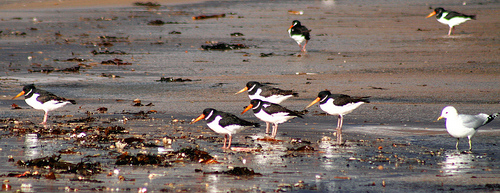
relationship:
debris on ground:
[0, 113, 270, 188] [1, 2, 498, 189]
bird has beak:
[431, 104, 495, 153] [435, 113, 444, 123]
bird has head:
[431, 104, 495, 153] [441, 103, 458, 119]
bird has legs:
[187, 107, 263, 147] [331, 112, 349, 138]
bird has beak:
[231, 92, 308, 139] [235, 94, 263, 123]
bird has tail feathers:
[431, 104, 495, 153] [478, 109, 497, 127]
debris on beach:
[63, 40, 206, 87] [7, 3, 447, 191]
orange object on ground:
[368, 140, 389, 155] [1, 2, 498, 189]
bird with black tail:
[437, 104, 499, 156] [485, 110, 498, 122]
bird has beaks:
[187, 107, 263, 147] [188, 113, 205, 124]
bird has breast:
[187, 87, 249, 148] [198, 115, 229, 142]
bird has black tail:
[302, 90, 376, 131] [356, 94, 372, 104]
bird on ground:
[187, 107, 263, 147] [1, 0, 493, 188]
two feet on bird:
[221, 135, 233, 152] [431, 104, 495, 153]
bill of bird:
[298, 94, 326, 124] [416, 97, 495, 154]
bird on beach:
[301, 84, 379, 144] [3, 7, 496, 137]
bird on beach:
[234, 72, 296, 114] [7, 3, 447, 191]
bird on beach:
[282, 15, 321, 58] [2, 2, 492, 165]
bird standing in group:
[10, 80, 78, 123] [11, 5, 484, 156]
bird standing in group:
[187, 107, 263, 147] [11, 5, 484, 156]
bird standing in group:
[237, 98, 309, 138] [11, 5, 484, 156]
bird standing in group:
[302, 90, 376, 131] [11, 5, 484, 156]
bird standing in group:
[286, 19, 314, 57] [11, 5, 484, 156]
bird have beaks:
[187, 107, 263, 147] [184, 111, 213, 129]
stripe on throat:
[322, 89, 330, 100] [318, 77, 334, 107]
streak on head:
[178, 96, 264, 150] [201, 106, 213, 118]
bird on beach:
[187, 107, 263, 147] [7, 3, 447, 191]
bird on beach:
[431, 104, 495, 153] [7, 3, 447, 191]